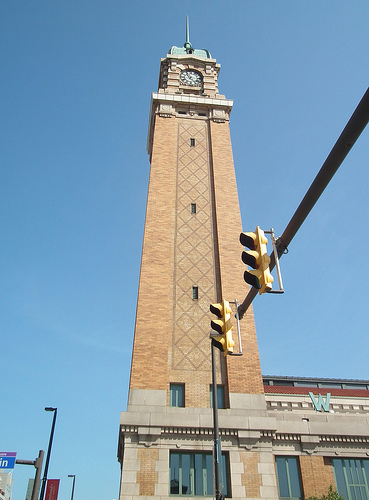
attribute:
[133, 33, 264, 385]
tower — brick, tall, red, massive, shining, here, tan, huge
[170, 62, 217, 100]
clock — tall, high, gold, close, black, roman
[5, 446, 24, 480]
sign — below, blue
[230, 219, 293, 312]
light — hanging, yellow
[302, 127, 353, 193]
pole — metal, black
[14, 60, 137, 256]
sky — high, light, blue